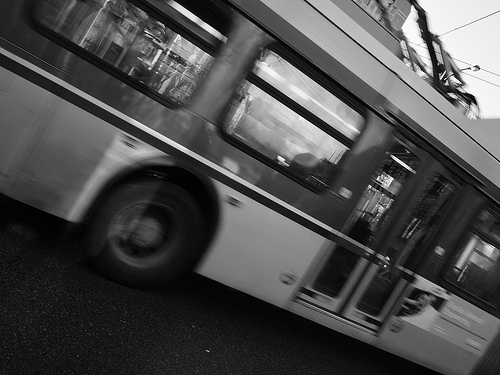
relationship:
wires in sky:
[391, 1, 498, 95] [396, 0, 498, 120]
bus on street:
[1, 1, 498, 373] [2, 202, 439, 373]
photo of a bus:
[4, 0, 498, 368] [1, 1, 498, 373]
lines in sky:
[431, 5, 494, 66] [440, 2, 498, 48]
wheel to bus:
[88, 163, 220, 283] [1, 1, 498, 373]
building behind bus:
[351, 0, 413, 35] [1, 1, 498, 373]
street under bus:
[2, 202, 439, 373] [1, 1, 498, 373]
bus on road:
[91, 169, 215, 297] [6, 233, 290, 365]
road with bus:
[8, 217, 332, 373] [1, 1, 498, 373]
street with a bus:
[2, 202, 439, 373] [1, 1, 498, 373]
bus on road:
[1, 1, 498, 373] [45, 198, 262, 361]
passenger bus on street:
[4, 3, 499, 373] [35, 303, 242, 368]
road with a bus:
[8, 217, 332, 373] [1, 1, 498, 373]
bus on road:
[1, 1, 498, 373] [0, 195, 210, 373]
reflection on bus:
[66, 85, 267, 220] [1, 1, 498, 373]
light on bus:
[224, 195, 244, 212] [1, 1, 498, 373]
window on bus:
[149, 28, 211, 102] [247, 30, 499, 360]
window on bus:
[219, 39, 370, 196] [1, 1, 498, 373]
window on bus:
[219, 39, 370, 196] [0, 5, 492, 318]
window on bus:
[219, 39, 370, 196] [11, 58, 492, 373]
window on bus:
[219, 39, 370, 196] [85, 14, 499, 341]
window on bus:
[432, 191, 499, 315] [1, 1, 498, 373]